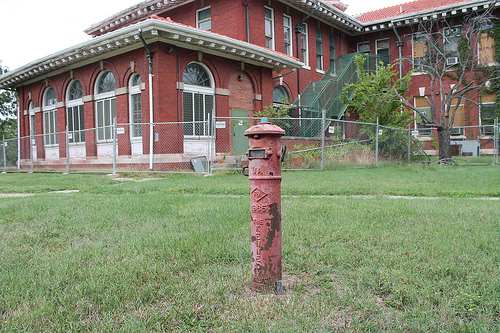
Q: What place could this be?
A: It is a yard.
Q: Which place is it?
A: It is a yard.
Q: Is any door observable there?
A: Yes, there is a door.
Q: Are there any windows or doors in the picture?
A: Yes, there is a door.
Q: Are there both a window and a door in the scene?
A: Yes, there are both a door and a window.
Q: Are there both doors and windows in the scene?
A: Yes, there are both a door and a window.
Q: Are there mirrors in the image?
A: No, there are no mirrors.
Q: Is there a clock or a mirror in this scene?
A: No, there are no mirrors or clocks.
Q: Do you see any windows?
A: Yes, there is a window.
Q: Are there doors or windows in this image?
A: Yes, there is a window.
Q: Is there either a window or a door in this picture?
A: Yes, there is a window.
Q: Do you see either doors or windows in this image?
A: Yes, there is a window.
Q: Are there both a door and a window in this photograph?
A: Yes, there are both a window and a door.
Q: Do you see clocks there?
A: No, there are no clocks.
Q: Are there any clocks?
A: No, there are no clocks.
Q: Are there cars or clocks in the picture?
A: No, there are no clocks or cars.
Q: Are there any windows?
A: Yes, there is a window.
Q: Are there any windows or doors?
A: Yes, there is a window.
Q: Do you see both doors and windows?
A: Yes, there are both a window and a door.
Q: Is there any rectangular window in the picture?
A: Yes, there is a rectangular window.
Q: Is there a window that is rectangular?
A: Yes, there is a window that is rectangular.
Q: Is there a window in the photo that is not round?
A: Yes, there is a rectangular window.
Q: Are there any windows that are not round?
A: Yes, there is a rectangular window.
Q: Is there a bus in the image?
A: No, there are no buses.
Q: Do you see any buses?
A: No, there are no buses.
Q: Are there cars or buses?
A: No, there are no buses or cars.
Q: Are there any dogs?
A: No, there are no dogs.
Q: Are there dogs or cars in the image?
A: No, there are no dogs or cars.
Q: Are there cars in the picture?
A: No, there are no cars.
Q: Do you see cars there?
A: No, there are no cars.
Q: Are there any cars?
A: No, there are no cars.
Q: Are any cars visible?
A: No, there are no cars.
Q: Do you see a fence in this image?
A: Yes, there is a fence.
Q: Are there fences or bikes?
A: Yes, there is a fence.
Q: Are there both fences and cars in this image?
A: No, there is a fence but no cars.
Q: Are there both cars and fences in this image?
A: No, there is a fence but no cars.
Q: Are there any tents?
A: No, there are no tents.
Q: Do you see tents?
A: No, there are no tents.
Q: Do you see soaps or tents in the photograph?
A: No, there are no tents or soaps.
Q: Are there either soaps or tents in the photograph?
A: No, there are no tents or soaps.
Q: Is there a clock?
A: No, there are no clocks.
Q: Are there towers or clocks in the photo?
A: No, there are no clocks or towers.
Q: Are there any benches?
A: No, there are no benches.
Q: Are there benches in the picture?
A: No, there are no benches.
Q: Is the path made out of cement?
A: Yes, the path is made of cement.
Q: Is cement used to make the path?
A: Yes, the path is made of cement.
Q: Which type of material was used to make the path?
A: The path is made of concrete.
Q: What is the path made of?
A: The path is made of concrete.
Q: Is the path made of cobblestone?
A: No, the path is made of concrete.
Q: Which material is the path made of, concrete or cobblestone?
A: The path is made of concrete.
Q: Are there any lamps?
A: No, there are no lamps.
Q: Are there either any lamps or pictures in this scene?
A: No, there are no lamps or pictures.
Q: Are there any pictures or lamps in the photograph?
A: No, there are no lamps or pictures.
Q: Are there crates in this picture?
A: No, there are no crates.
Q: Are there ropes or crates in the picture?
A: No, there are no crates or ropes.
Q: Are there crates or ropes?
A: No, there are no crates or ropes.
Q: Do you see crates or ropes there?
A: No, there are no crates or ropes.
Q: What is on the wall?
A: The drain is on the wall.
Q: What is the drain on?
A: The drain is on the wall.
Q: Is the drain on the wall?
A: Yes, the drain is on the wall.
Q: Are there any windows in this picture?
A: Yes, there are windows.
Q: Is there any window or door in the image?
A: Yes, there are windows.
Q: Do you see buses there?
A: No, there are no buses.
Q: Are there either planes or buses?
A: No, there are no buses or planes.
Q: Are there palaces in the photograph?
A: No, there are no palaces.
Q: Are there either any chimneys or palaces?
A: No, there are no palaces or chimneys.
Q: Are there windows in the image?
A: Yes, there is a window.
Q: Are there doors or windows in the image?
A: Yes, there is a window.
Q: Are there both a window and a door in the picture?
A: Yes, there are both a window and a door.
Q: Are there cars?
A: No, there are no cars.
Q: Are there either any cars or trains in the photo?
A: No, there are no cars or trains.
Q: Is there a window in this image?
A: Yes, there is a window.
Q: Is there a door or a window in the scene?
A: Yes, there is a window.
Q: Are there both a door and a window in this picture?
A: Yes, there are both a window and a door.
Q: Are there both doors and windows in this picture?
A: Yes, there are both a window and a door.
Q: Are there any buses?
A: No, there are no buses.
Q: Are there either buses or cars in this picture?
A: No, there are no buses or cars.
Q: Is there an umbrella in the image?
A: No, there are no umbrellas.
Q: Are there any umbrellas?
A: No, there are no umbrellas.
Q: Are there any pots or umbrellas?
A: No, there are no umbrellas or pots.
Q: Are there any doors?
A: Yes, there are doors.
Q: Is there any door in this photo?
A: Yes, there are doors.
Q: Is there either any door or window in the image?
A: Yes, there are doors.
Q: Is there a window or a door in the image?
A: Yes, there are doors.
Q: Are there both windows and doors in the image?
A: Yes, there are both doors and a window.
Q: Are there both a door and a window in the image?
A: Yes, there are both a door and a window.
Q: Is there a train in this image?
A: No, there are no trains.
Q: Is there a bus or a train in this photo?
A: No, there are no trains or buses.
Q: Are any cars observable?
A: No, there are no cars.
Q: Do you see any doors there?
A: Yes, there is a door.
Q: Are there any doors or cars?
A: Yes, there is a door.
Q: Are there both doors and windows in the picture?
A: Yes, there are both a door and a window.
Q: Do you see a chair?
A: No, there are no chairs.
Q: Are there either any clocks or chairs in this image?
A: No, there are no chairs or clocks.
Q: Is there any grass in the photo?
A: Yes, there is grass.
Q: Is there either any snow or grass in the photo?
A: Yes, there is grass.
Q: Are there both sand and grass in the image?
A: No, there is grass but no sand.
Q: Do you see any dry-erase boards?
A: No, there are no dry-erase boards.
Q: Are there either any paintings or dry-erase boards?
A: No, there are no dry-erase boards or paintings.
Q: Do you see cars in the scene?
A: No, there are no cars.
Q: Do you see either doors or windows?
A: Yes, there is a window.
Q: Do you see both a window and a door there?
A: Yes, there are both a window and a door.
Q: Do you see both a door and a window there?
A: Yes, there are both a window and a door.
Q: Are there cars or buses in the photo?
A: No, there are no cars or buses.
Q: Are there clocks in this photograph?
A: No, there are no clocks.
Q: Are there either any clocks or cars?
A: No, there are no clocks or cars.